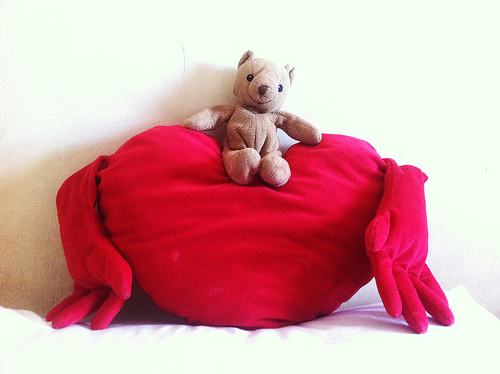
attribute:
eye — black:
[244, 70, 253, 81]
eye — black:
[277, 82, 284, 93]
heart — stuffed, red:
[39, 114, 454, 334]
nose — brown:
[257, 83, 266, 97]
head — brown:
[234, 50, 295, 112]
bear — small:
[185, 50, 322, 186]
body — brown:
[186, 105, 321, 185]